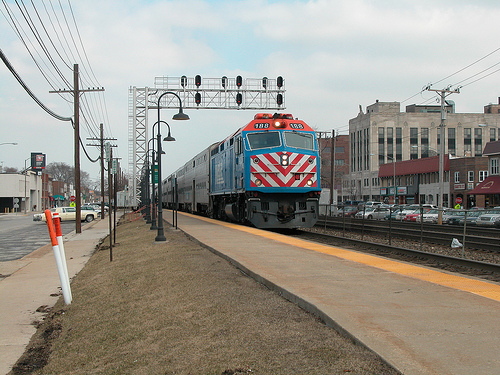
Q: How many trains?
A: One.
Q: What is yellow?
A: Stripe.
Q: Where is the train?
A: On the tracks.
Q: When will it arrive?
A: Now.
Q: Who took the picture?
A: Man.